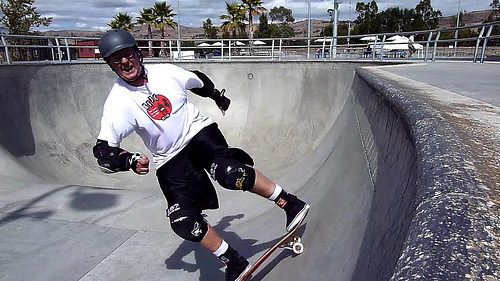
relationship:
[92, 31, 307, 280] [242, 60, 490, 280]
man riding on ramp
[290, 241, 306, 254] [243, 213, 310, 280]
wheel of skateboard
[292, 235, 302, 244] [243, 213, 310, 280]
wheel of skateboard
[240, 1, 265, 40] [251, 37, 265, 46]
palm near umbrella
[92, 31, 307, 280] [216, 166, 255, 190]
man wearing a knee knee-pad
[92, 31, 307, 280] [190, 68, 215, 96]
man wearing an elbow-pad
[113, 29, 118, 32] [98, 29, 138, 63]
hole in helmet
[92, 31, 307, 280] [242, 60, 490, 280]
man on ramp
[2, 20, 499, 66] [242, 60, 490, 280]
rail along ramp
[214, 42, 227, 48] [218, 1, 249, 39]
umbrella near palm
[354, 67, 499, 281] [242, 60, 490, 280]
rim of ramp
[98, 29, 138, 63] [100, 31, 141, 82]
helmet on head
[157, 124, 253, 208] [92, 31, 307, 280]
shorts on man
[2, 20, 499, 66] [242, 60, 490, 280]
rail around ramp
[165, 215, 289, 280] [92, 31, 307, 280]
shadow of man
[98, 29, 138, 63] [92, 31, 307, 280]
helmet on man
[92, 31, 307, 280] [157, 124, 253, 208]
man wearing shorts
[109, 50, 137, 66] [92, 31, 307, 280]
glasses on man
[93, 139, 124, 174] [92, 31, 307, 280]
elbow-pad worn by man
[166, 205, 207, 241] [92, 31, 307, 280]
knee-pad on man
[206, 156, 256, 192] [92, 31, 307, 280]
knee-pad on man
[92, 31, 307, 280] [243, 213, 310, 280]
man riding on skateboard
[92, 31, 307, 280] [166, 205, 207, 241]
man wearing knee-pad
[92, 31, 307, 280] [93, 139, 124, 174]
man wearing elbow-pad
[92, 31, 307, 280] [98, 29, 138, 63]
man wearing helmet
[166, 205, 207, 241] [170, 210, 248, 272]
knee-pad on leg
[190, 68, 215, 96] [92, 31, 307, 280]
elbow-pad on man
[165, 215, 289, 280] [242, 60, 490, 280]
shadow on ramp